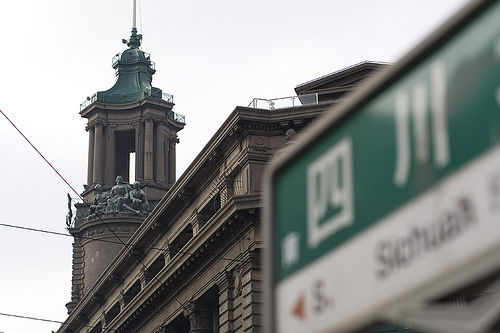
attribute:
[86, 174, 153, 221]
statues — Green 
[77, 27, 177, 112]
roof — Green 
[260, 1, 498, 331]
sign — Green 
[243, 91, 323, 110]
fence — Glass 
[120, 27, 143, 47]
statue — Green 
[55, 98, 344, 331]
roof — flat 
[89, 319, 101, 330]
window — narrow 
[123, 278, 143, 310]
window — narrow 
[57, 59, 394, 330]
building — narrow 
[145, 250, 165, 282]
window — narrow 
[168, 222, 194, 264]
window — narrow 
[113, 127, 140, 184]
window — Long , narrow 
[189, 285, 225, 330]
window — narrow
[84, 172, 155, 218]
statue — small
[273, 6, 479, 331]
sign — street , green, white, Blurred street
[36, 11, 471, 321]
building — copper statue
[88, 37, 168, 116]
building — top, green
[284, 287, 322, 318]
sign — orange arrow ,  street 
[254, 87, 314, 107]
railing —  top  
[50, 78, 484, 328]
building —  top  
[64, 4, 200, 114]
tower —  top  ,  copper 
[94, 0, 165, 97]
tower — steeple copper top , building 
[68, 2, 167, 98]
tower — building , copper statue 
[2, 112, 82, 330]
line — black electrical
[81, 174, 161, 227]
man — statue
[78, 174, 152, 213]
woman — statue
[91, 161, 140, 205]
man — statue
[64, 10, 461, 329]
building — edge , metal fence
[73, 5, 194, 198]
tower — top, Flagpole 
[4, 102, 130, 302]
wires — Criss crossing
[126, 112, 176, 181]
columns — Decorative 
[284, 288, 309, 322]
arrow — red , pointing left.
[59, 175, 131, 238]
deck — Observation 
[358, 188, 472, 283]
word — Blurred 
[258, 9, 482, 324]
sign — white , green 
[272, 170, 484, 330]
sign — white trim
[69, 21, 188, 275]
tower — green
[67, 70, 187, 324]
cables — group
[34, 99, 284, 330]
building — brown